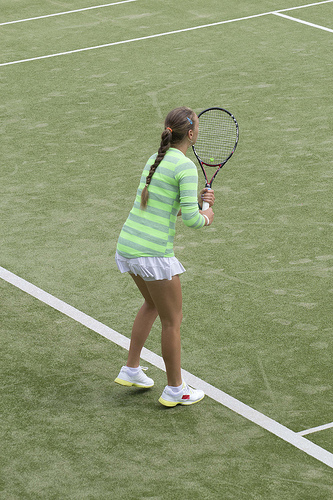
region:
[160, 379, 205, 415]
the woman is wearing white tennis shoes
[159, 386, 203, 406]
the woman is wearing white and yellow tennis shoes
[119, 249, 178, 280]
the woman is wearing a white skirt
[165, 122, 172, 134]
the woman is wearing an orange band in her hair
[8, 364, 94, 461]
a green tennis court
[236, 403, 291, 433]
white lines on the tennis court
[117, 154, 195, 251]
a woman is wearing a green and grey shirt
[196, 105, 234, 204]
woman is holding a black tennis racket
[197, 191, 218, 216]
white handle on the tennis racket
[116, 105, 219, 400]
woman playing tennis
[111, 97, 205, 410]
Tennis player holding racket.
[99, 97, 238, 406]
Tennis player on court.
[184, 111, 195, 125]
Blue barrette worn by player.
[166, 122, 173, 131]
Orange hair band worn by player.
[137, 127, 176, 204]
Player's long brown braid.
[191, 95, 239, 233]
Tennis racket held by player.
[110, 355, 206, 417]
White and yellow.shoes worn by player.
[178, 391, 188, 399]
Red square on player's shoe.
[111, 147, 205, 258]
Green and grey top worn by player.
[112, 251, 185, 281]
White skort worn by player.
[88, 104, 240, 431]
this is a tennis player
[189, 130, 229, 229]
she is holding a racket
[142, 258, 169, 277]
the skirt is white in color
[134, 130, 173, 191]
this is the hair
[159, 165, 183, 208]
the blouse is green in color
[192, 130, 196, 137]
the player is light skinned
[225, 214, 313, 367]
the pitch is green in collor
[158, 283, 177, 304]
the player is light skinned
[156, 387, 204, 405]
the shoes are white in color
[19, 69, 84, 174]
The ground is the color green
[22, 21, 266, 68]
The line on the ground is the color white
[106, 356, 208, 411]
The shoes of the woman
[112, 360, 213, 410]
The shoes are yellow and white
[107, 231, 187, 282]
The tennis skirt is white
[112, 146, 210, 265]
The woman is wearing a shirt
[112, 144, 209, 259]
The shirt is the color green and grey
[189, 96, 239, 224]
The woman is holding a tennis racket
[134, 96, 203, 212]
The woman has brown hair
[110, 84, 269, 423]
The woman is playing tennis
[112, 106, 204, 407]
A woman playing tennis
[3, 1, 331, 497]
Green tennis court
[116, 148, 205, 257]
Long sleeve shirt on the woman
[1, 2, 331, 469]
White lines on the tennis court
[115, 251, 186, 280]
White shorts on the woman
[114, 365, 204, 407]
Shoes on the woman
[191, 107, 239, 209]
Racket in the woman's hands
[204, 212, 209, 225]
White band on the woman's wrist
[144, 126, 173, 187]
Hair bands on the woman's hair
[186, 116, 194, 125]
Hair pin on the woman's head